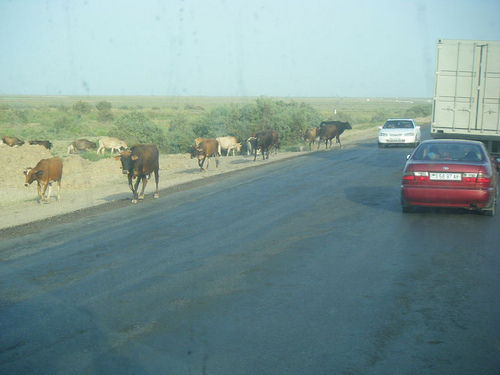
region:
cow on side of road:
[103, 142, 170, 211]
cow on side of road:
[17, 154, 69, 201]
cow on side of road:
[253, 133, 269, 160]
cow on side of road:
[318, 128, 340, 150]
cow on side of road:
[66, 127, 96, 157]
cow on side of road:
[99, 135, 127, 150]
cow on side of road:
[2, 140, 22, 150]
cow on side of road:
[38, 138, 66, 150]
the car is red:
[394, 135, 496, 208]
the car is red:
[373, 116, 485, 230]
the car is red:
[383, 125, 475, 211]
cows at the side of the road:
[32, 112, 229, 236]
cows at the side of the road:
[12, 140, 216, 224]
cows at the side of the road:
[180, 110, 297, 202]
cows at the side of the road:
[266, 98, 377, 177]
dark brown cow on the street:
[116, 141, 162, 205]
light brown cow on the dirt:
[21, 157, 65, 203]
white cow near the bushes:
[95, 133, 128, 160]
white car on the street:
[373, 115, 422, 149]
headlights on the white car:
[378, 128, 418, 140]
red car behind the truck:
[398, 135, 499, 215]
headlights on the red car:
[399, 165, 493, 189]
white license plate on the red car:
[426, 169, 464, 182]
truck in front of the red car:
[429, 34, 499, 141]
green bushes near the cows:
[1, 96, 340, 148]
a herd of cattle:
[9, 100, 351, 225]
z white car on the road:
[373, 115, 424, 147]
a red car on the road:
[397, 136, 492, 219]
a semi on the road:
[428, 33, 496, 132]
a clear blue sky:
[19, 2, 428, 92]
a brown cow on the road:
[113, 139, 164, 204]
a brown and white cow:
[19, 152, 66, 207]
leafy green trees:
[215, 98, 313, 140]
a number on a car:
[429, 171, 458, 182]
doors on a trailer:
[438, 40, 491, 127]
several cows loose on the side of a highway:
[16, 116, 356, 212]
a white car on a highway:
[373, 116, 422, 151]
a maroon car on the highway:
[397, 137, 498, 220]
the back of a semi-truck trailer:
[431, 30, 496, 137]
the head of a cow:
[19, 162, 38, 192]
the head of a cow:
[112, 148, 138, 175]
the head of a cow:
[342, 119, 352, 131]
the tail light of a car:
[399, 166, 430, 186]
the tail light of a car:
[460, 169, 490, 186]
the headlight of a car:
[376, 133, 387, 143]